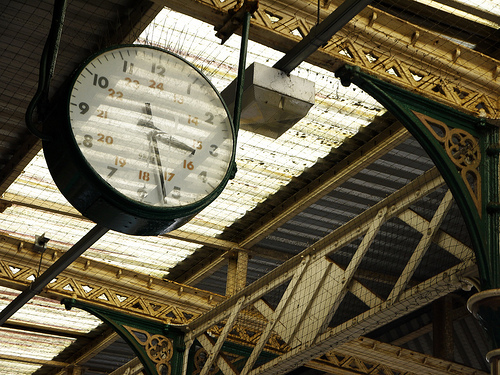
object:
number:
[147, 55, 169, 80]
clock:
[35, 32, 254, 243]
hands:
[136, 116, 198, 160]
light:
[197, 34, 239, 54]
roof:
[296, 106, 400, 218]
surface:
[315, 178, 373, 232]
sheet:
[257, 98, 372, 203]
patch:
[78, 5, 119, 45]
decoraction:
[307, 120, 379, 164]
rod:
[372, 73, 480, 159]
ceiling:
[14, 23, 63, 68]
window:
[297, 114, 367, 155]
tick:
[139, 99, 172, 201]